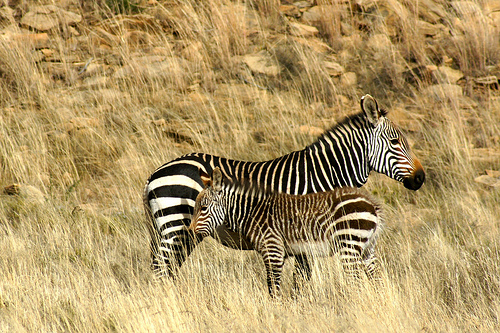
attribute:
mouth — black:
[402, 169, 425, 191]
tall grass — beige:
[5, 9, 305, 144]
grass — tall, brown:
[396, 231, 476, 315]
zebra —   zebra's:
[183, 170, 413, 266]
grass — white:
[7, 220, 181, 324]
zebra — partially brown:
[183, 164, 423, 312]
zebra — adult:
[131, 73, 451, 299]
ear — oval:
[344, 79, 389, 131]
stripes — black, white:
[148, 150, 211, 282]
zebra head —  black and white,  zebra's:
[361, 93, 426, 190]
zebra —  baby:
[168, 170, 390, 278]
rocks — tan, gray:
[2, 3, 499, 128]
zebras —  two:
[144, 77, 410, 264]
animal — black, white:
[170, 182, 394, 252]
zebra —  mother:
[144, 92, 427, 297]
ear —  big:
[362, 92, 382, 126]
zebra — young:
[181, 171, 384, 301]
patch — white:
[286, 242, 337, 255]